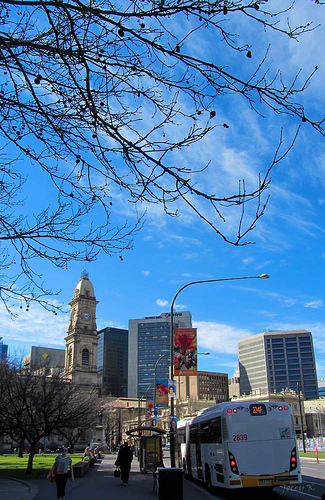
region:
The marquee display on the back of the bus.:
[250, 399, 267, 412]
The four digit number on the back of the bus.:
[227, 432, 253, 444]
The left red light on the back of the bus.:
[227, 459, 236, 466]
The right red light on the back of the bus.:
[289, 455, 299, 461]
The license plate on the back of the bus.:
[256, 477, 272, 485]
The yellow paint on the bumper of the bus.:
[236, 474, 291, 485]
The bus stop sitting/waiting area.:
[126, 422, 170, 472]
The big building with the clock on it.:
[71, 264, 100, 380]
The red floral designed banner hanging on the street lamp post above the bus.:
[173, 326, 200, 373]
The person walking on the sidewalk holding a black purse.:
[105, 433, 134, 485]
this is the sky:
[156, 230, 210, 269]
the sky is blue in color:
[107, 280, 132, 302]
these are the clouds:
[201, 330, 223, 340]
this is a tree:
[23, 206, 121, 251]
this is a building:
[263, 335, 302, 370]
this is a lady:
[48, 446, 78, 498]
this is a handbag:
[111, 468, 120, 478]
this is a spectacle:
[61, 447, 66, 449]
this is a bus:
[199, 409, 290, 477]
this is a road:
[86, 479, 111, 498]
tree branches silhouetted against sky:
[3, 0, 255, 210]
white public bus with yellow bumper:
[171, 399, 304, 488]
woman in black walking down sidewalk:
[112, 439, 133, 486]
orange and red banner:
[170, 325, 198, 376]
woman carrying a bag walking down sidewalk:
[45, 445, 77, 498]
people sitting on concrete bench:
[79, 443, 103, 467]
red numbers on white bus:
[229, 430, 250, 442]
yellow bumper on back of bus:
[238, 471, 291, 487]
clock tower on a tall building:
[61, 267, 100, 380]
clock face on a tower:
[81, 310, 91, 320]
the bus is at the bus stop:
[174, 400, 301, 486]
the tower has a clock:
[67, 269, 98, 373]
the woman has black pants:
[50, 447, 74, 497]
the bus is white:
[171, 401, 301, 488]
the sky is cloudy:
[0, 1, 324, 378]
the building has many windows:
[238, 329, 318, 399]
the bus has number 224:
[250, 405, 263, 414]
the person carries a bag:
[115, 469, 119, 476]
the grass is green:
[0, 447, 97, 468]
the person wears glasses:
[63, 448, 68, 450]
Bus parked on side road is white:
[183, 395, 309, 495]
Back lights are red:
[220, 452, 302, 471]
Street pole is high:
[156, 256, 274, 327]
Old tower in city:
[54, 261, 108, 378]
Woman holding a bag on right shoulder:
[44, 441, 78, 498]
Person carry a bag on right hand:
[109, 439, 136, 487]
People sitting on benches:
[78, 436, 106, 468]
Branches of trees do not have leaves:
[3, 0, 323, 282]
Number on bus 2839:
[229, 429, 251, 445]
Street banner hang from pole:
[168, 323, 201, 381]